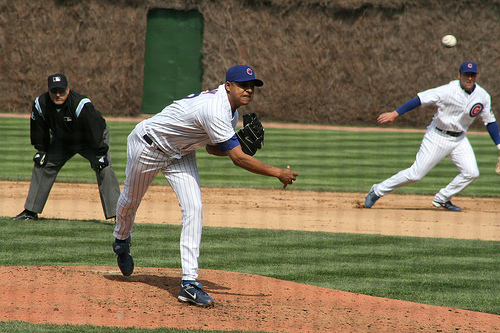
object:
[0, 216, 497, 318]
lawn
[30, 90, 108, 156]
jacket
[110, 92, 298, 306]
body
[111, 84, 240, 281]
uniform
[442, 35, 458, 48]
ball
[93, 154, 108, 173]
hands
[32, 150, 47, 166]
hands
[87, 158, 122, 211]
legs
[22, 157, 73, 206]
legs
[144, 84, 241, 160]
jacket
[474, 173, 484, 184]
ground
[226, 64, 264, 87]
cap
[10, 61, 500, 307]
people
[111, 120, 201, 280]
white pants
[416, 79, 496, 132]
white shirt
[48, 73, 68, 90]
cap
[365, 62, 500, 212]
baseball player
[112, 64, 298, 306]
baseball player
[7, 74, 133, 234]
baseball player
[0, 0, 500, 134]
wall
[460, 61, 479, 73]
cap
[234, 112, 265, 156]
glove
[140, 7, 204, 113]
door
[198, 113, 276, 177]
arm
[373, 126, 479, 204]
pants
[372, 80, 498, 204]
team uniform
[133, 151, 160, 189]
stripes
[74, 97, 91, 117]
stripes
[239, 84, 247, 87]
eyes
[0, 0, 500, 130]
camp